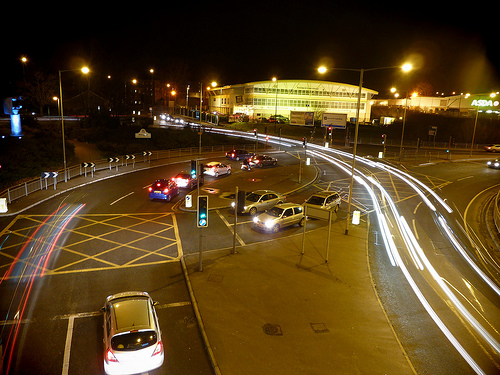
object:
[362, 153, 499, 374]
street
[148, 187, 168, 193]
light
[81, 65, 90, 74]
light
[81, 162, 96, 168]
sign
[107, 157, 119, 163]
sign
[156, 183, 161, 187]
light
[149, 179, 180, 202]
car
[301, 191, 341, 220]
car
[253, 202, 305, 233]
car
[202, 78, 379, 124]
building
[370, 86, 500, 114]
asda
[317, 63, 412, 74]
lights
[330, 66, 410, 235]
pole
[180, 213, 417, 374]
median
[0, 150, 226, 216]
sidewalk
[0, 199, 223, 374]
lane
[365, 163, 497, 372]
lane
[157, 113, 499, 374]
lane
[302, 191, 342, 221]
van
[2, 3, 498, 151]
sky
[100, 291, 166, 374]
car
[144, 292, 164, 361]
side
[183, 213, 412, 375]
concrete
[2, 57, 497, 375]
street city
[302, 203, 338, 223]
sign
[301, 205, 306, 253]
pole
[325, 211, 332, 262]
pole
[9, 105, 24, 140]
blue sign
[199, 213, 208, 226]
green traffic-light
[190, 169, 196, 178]
green traffic-light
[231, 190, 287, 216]
silver sedan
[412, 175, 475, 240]
dash line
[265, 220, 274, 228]
light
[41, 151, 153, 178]
signs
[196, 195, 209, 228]
stop light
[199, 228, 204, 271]
pole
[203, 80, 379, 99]
roof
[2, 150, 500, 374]
lines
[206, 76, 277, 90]
lights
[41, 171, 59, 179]
sign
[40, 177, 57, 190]
pole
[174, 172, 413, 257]
right turn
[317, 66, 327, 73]
light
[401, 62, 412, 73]
light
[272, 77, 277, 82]
light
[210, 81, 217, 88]
light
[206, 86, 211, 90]
light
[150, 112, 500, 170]
intersection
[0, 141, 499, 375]
intersection